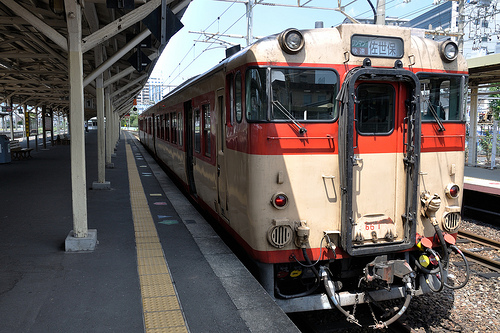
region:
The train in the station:
[133, 21, 475, 323]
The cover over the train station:
[2, 0, 194, 258]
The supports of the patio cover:
[62, 0, 120, 255]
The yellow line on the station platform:
[120, 129, 190, 331]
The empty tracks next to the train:
[456, 226, 498, 271]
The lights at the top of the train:
[280, 26, 459, 65]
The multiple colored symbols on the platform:
[127, 134, 181, 229]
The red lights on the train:
[271, 183, 461, 210]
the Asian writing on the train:
[367, 36, 405, 58]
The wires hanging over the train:
[145, 0, 495, 100]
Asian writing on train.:
[333, 25, 410, 109]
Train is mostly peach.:
[243, 150, 368, 270]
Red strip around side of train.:
[160, 108, 335, 146]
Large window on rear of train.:
[234, 53, 389, 135]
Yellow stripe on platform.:
[108, 148, 172, 327]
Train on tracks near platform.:
[203, 172, 427, 317]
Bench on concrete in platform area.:
[7, 135, 45, 185]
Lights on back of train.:
[281, 24, 477, 60]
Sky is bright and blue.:
[181, 34, 238, 66]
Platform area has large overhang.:
[26, 28, 161, 150]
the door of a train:
[338, 62, 422, 245]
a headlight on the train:
[277, 25, 311, 55]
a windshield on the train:
[248, 61, 340, 126]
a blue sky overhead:
[138, 0, 450, 107]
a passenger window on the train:
[197, 98, 212, 160]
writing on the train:
[346, 31, 407, 60]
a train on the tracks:
[131, 17, 476, 331]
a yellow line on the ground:
[123, 121, 198, 331]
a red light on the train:
[265, 187, 290, 212]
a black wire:
[306, 235, 420, 331]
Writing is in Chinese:
[341, 27, 406, 64]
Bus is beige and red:
[257, 27, 468, 287]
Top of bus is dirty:
[261, 22, 468, 73]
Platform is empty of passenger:
[20, 117, 159, 331]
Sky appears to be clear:
[195, 3, 317, 33]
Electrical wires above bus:
[176, 0, 267, 67]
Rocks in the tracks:
[473, 220, 495, 302]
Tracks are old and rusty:
[466, 227, 498, 299]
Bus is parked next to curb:
[126, 48, 351, 331]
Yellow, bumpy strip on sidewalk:
[121, 156, 183, 328]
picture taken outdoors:
[177, 33, 454, 274]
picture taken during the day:
[201, 12, 451, 229]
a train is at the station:
[195, 24, 481, 252]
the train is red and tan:
[236, 76, 473, 218]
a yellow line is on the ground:
[113, 174, 145, 306]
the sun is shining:
[192, 16, 466, 254]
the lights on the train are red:
[295, 179, 496, 199]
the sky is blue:
[167, 59, 188, 74]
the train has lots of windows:
[145, 114, 248, 152]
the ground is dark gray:
[40, 259, 125, 331]